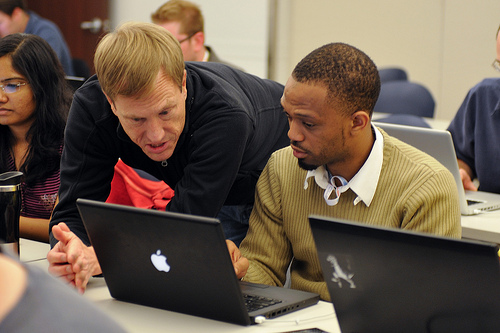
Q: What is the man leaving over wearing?
A: A black shirt.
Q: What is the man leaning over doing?
A: Giving some instruction to the other person.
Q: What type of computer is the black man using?
A: Apple.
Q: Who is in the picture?
A: Men and women.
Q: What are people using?
A: Computers.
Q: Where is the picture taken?
A: A classroom.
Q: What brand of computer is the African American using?
A: Apple.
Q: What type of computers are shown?
A: Laptops.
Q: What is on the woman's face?
A: Glasses.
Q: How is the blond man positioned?
A: Leaning.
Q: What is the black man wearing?
A: Ribbed sweater.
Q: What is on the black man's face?
A: A beard.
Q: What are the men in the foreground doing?
A: Talking.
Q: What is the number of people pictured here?
A: Six.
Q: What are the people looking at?
A: Laptops.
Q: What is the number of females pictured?
A: One.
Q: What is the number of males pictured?
A: Five.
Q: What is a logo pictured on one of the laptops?
A: Apple.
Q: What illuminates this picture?
A: Indoor lighting.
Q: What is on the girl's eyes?
A: A pair of glasses.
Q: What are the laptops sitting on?
A: Long tables.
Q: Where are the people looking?
A: At the laptop.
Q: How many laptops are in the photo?
A: Three.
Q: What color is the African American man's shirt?
A: Tan.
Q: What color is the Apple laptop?
A: Black.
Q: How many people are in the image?
A: Seven.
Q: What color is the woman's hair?
A: Black.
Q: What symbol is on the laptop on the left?
A: An apple.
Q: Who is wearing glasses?
A: The woman.